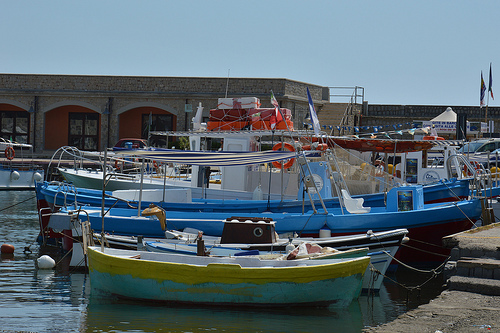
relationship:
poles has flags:
[475, 67, 484, 115] [468, 53, 498, 115]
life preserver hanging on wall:
[271, 142, 296, 167] [251, 143, 300, 204]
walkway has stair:
[446, 222, 498, 291] [442, 235, 500, 297]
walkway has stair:
[446, 222, 498, 291] [456, 256, 485, 279]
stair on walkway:
[442, 235, 500, 297] [446, 222, 498, 291]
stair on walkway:
[456, 256, 485, 279] [446, 222, 498, 291]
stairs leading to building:
[135, 169, 498, 294] [42, 79, 304, 153]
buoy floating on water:
[1, 240, 16, 255] [1, 188, 452, 330]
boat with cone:
[57, 106, 478, 208] [203, 105, 256, 129]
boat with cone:
[57, 106, 478, 208] [250, 101, 292, 128]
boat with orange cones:
[58, 97, 469, 192] [201, 110, 305, 133]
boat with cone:
[104, 126, 352, 296] [232, 113, 293, 155]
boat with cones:
[39, 106, 489, 264] [214, 91, 332, 133]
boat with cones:
[431, 115, 473, 143] [438, 99, 443, 107]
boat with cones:
[37, 89, 482, 259] [208, 100, 297, 125]